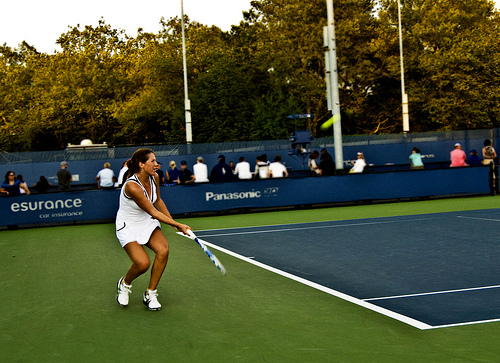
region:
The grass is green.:
[206, 304, 282, 361]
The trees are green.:
[76, 24, 366, 119]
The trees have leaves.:
[121, 23, 344, 119]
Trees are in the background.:
[116, 20, 394, 120]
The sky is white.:
[0, 1, 55, 36]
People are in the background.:
[179, 142, 381, 192]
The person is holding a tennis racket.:
[174, 214, 239, 278]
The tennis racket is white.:
[179, 217, 236, 277]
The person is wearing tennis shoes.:
[106, 270, 168, 317]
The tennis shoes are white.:
[106, 272, 189, 323]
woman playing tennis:
[115, 141, 228, 321]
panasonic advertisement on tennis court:
[198, 185, 286, 203]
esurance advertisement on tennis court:
[8, 196, 95, 218]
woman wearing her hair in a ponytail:
[124, 141, 159, 183]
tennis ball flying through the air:
[319, 109, 342, 133]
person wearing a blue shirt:
[401, 141, 426, 168]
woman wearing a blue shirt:
[3, 165, 29, 197]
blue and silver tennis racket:
[191, 232, 228, 277]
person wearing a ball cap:
[55, 153, 75, 188]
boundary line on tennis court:
[223, 248, 433, 329]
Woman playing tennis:
[103, 143, 233, 321]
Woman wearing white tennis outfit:
[112, 144, 232, 340]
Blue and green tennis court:
[160, 220, 484, 352]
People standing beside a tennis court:
[155, 147, 476, 184]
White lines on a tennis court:
[245, 266, 427, 340]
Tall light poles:
[174, 18, 379, 165]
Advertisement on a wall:
[0, 195, 105, 240]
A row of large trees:
[42, 15, 479, 150]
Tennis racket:
[165, 221, 236, 282]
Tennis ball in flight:
[295, 102, 357, 142]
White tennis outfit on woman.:
[121, 146, 174, 266]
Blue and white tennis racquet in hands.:
[160, 206, 235, 296]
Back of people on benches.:
[225, 143, 292, 178]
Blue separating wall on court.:
[287, 148, 395, 208]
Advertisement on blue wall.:
[192, 180, 299, 217]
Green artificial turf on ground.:
[99, 288, 259, 345]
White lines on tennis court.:
[324, 280, 438, 333]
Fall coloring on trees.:
[50, 45, 176, 120]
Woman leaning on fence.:
[2, 163, 34, 204]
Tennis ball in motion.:
[313, 108, 369, 146]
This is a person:
[444, 139, 470, 172]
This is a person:
[474, 133, 497, 171]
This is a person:
[409, 142, 424, 172]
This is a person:
[344, 144, 369, 179]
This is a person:
[269, 153, 291, 178]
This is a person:
[253, 148, 269, 185]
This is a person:
[230, 153, 255, 184]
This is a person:
[208, 150, 233, 185]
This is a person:
[190, 153, 212, 185]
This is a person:
[113, 144, 198, 318]